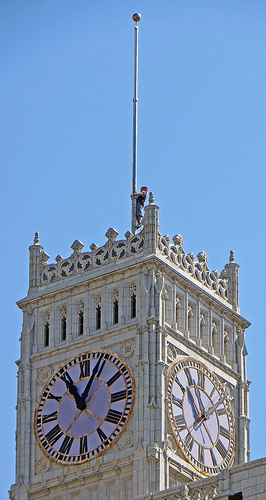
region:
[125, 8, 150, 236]
a kid on a pole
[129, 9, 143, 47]
a ball on top a pole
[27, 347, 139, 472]
a clock on front a clock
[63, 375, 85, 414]
hour hand of clock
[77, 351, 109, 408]
minute hand of clock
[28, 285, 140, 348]
narrow windows in a tower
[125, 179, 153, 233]
kid hugging a pole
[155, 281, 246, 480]
windows on top a clock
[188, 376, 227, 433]
the handles of clock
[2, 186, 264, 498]
the tower is color white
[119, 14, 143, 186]
metal flag pole on building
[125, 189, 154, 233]
person is holding flagpole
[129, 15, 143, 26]
silver ball atop flagpole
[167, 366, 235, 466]
white clock on tower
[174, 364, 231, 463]
roman numerals on clock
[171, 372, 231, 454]
roman numerals are black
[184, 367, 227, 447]
black hands on clock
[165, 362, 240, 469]
clock has gold border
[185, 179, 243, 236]
blue and clear sky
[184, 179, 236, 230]
no clouds in sky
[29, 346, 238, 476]
Clocks on a building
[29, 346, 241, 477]
Clocks are on a building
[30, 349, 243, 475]
Clocks on a tower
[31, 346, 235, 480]
Clocks are on a tower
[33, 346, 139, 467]
Clock on a building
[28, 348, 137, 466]
Clock is on a building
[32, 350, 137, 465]
Clock on a tower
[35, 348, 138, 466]
Clock is on a tower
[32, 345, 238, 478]
Large clocks are on a building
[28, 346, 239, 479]
Large clocks are on a tower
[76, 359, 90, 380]
roman numeral on clock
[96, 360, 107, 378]
roman numeral on clock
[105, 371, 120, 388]
roman numeral on clock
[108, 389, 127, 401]
roman numeral on clock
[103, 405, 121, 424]
roman numeral on clock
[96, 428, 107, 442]
roman numeral on clock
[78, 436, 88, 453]
roman numeral on clock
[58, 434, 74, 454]
roman numeral on clock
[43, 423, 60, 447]
roman numeral on clock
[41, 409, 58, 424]
roman numeral on clock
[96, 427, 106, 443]
roman numeral on clock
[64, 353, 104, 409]
the clock hands are black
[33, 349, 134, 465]
the clock has black hands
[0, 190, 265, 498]
the clocks on the tower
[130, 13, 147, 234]
the person holding onto the pole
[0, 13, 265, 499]
the pole on the tower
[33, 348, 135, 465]
the roman numerals on the clock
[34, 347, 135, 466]
the clock has gold accents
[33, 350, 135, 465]
the minute marks on the clock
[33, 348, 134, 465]
the clock has large black hands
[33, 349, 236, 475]
the two clocks are very large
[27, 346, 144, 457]
gold black and white clock in tower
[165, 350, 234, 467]
gold black and white clock in tower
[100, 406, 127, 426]
roman numeral on large clock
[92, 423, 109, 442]
roman numeral on large clock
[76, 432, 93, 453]
roman numeral on large clock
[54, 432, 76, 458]
roman numeral on large clock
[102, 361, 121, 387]
roman numeral on large clock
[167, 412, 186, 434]
roman numeral on large clock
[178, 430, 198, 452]
roman numeral on large clock